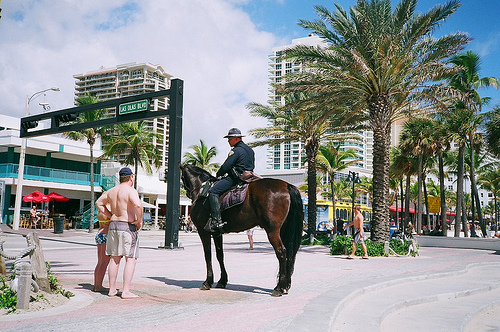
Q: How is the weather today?
A: It is cloudy.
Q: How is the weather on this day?
A: It is cloudy.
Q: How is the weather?
A: It is cloudy.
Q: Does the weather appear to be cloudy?
A: Yes, it is cloudy.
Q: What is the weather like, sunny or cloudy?
A: It is cloudy.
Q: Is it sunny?
A: No, it is cloudy.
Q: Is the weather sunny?
A: No, it is cloudy.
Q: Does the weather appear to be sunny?
A: No, it is cloudy.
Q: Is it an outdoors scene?
A: Yes, it is outdoors.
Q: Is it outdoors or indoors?
A: It is outdoors.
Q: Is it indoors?
A: No, it is outdoors.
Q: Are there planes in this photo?
A: No, there are no planes.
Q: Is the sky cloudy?
A: Yes, the sky is cloudy.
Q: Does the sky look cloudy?
A: Yes, the sky is cloudy.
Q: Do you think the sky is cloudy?
A: Yes, the sky is cloudy.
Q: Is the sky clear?
A: No, the sky is cloudy.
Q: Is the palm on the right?
A: Yes, the palm is on the right of the image.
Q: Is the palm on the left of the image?
A: No, the palm is on the right of the image.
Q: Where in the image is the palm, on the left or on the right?
A: The palm is on the right of the image.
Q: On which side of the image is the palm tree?
A: The palm tree is on the right of the image.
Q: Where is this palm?
A: The palm is on the street.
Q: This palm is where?
A: The palm is on the street.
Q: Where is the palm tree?
A: The palm is on the street.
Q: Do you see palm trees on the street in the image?
A: Yes, there is a palm tree on the street.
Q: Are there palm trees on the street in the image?
A: Yes, there is a palm tree on the street.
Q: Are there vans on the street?
A: No, there is a palm tree on the street.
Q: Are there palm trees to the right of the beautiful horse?
A: Yes, there is a palm tree to the right of the horse.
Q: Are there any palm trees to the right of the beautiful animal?
A: Yes, there is a palm tree to the right of the horse.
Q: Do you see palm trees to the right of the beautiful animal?
A: Yes, there is a palm tree to the right of the horse.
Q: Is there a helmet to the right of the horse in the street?
A: No, there is a palm tree to the right of the horse.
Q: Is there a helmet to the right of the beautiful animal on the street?
A: No, there is a palm tree to the right of the horse.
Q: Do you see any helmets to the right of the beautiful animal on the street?
A: No, there is a palm tree to the right of the horse.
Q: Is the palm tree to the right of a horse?
A: Yes, the palm tree is to the right of a horse.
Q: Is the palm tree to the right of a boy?
A: No, the palm tree is to the right of a horse.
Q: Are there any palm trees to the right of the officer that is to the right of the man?
A: Yes, there is a palm tree to the right of the officer.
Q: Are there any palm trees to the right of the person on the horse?
A: Yes, there is a palm tree to the right of the officer.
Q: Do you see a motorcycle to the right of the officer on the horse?
A: No, there is a palm tree to the right of the officer.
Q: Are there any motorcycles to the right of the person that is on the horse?
A: No, there is a palm tree to the right of the officer.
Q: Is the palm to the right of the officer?
A: Yes, the palm is to the right of the officer.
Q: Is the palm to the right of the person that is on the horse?
A: Yes, the palm is to the right of the officer.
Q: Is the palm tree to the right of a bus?
A: No, the palm tree is to the right of the officer.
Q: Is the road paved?
A: Yes, the road is paved.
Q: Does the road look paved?
A: Yes, the road is paved.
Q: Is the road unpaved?
A: No, the road is paved.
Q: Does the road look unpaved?
A: No, the road is paved.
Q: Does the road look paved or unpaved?
A: The road is paved.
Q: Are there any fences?
A: No, there are no fences.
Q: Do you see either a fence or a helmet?
A: No, there are no fences or helmets.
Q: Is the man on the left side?
A: Yes, the man is on the left of the image.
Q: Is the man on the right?
A: No, the man is on the left of the image.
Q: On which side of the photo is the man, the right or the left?
A: The man is on the left of the image.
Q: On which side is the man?
A: The man is on the left of the image.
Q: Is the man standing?
A: Yes, the man is standing.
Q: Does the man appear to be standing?
A: Yes, the man is standing.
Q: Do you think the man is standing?
A: Yes, the man is standing.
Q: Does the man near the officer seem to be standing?
A: Yes, the man is standing.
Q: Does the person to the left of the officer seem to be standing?
A: Yes, the man is standing.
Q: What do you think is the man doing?
A: The man is standing.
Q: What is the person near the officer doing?
A: The man is standing.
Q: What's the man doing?
A: The man is standing.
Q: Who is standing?
A: The man is standing.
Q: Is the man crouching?
A: No, the man is standing.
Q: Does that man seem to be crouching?
A: No, the man is standing.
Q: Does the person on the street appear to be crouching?
A: No, the man is standing.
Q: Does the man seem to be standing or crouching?
A: The man is standing.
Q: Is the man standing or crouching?
A: The man is standing.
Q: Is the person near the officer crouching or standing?
A: The man is standing.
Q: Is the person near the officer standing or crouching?
A: The man is standing.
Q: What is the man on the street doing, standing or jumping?
A: The man is standing.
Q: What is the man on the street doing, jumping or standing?
A: The man is standing.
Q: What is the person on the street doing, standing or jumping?
A: The man is standing.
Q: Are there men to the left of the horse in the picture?
A: Yes, there is a man to the left of the horse.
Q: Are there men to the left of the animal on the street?
A: Yes, there is a man to the left of the horse.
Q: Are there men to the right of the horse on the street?
A: No, the man is to the left of the horse.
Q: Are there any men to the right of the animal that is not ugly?
A: No, the man is to the left of the horse.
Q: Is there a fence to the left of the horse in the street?
A: No, there is a man to the left of the horse.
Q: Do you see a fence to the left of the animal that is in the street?
A: No, there is a man to the left of the horse.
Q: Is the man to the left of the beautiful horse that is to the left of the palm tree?
A: Yes, the man is to the left of the horse.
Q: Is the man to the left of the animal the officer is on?
A: Yes, the man is to the left of the horse.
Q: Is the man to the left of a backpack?
A: No, the man is to the left of the horse.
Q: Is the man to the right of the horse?
A: No, the man is to the left of the horse.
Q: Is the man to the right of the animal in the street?
A: No, the man is to the left of the horse.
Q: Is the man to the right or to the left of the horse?
A: The man is to the left of the horse.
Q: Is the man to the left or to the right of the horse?
A: The man is to the left of the horse.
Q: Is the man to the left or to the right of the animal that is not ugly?
A: The man is to the left of the horse.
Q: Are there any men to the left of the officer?
A: Yes, there is a man to the left of the officer.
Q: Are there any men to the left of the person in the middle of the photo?
A: Yes, there is a man to the left of the officer.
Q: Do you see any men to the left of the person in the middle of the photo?
A: Yes, there is a man to the left of the officer.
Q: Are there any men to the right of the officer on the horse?
A: No, the man is to the left of the officer.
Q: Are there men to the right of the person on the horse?
A: No, the man is to the left of the officer.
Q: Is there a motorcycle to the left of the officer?
A: No, there is a man to the left of the officer.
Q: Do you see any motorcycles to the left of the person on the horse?
A: No, there is a man to the left of the officer.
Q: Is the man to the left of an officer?
A: Yes, the man is to the left of an officer.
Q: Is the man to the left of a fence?
A: No, the man is to the left of an officer.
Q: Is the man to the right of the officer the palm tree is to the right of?
A: No, the man is to the left of the officer.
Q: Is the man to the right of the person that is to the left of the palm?
A: No, the man is to the left of the officer.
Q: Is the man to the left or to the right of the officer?
A: The man is to the left of the officer.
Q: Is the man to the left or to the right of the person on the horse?
A: The man is to the left of the officer.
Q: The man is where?
A: The man is on the street.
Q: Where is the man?
A: The man is on the street.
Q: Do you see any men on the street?
A: Yes, there is a man on the street.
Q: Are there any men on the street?
A: Yes, there is a man on the street.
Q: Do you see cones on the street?
A: No, there is a man on the street.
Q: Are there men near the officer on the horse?
A: Yes, there is a man near the officer.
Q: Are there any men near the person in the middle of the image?
A: Yes, there is a man near the officer.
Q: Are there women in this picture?
A: No, there are no women.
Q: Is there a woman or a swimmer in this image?
A: No, there are no women or swimmers.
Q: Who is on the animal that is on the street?
A: The officer is on the horse.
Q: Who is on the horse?
A: The officer is on the horse.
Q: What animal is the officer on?
A: The officer is on the horse.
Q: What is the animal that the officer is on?
A: The animal is a horse.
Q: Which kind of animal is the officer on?
A: The officer is on the horse.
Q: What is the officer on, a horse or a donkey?
A: The officer is on a horse.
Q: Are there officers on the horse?
A: Yes, there is an officer on the horse.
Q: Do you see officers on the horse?
A: Yes, there is an officer on the horse.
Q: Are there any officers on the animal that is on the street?
A: Yes, there is an officer on the horse.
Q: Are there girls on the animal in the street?
A: No, there is an officer on the horse.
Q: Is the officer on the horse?
A: Yes, the officer is on the horse.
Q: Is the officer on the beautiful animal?
A: Yes, the officer is on the horse.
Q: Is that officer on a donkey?
A: No, the officer is on the horse.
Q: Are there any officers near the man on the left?
A: Yes, there is an officer near the man.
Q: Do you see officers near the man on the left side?
A: Yes, there is an officer near the man.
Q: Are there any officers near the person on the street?
A: Yes, there is an officer near the man.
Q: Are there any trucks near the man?
A: No, there is an officer near the man.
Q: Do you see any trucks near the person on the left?
A: No, there is an officer near the man.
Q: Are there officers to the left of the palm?
A: Yes, there is an officer to the left of the palm.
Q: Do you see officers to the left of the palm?
A: Yes, there is an officer to the left of the palm.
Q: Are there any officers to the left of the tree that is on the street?
A: Yes, there is an officer to the left of the palm.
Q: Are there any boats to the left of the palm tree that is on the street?
A: No, there is an officer to the left of the palm tree.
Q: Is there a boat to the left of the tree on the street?
A: No, there is an officer to the left of the palm tree.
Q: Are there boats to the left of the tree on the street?
A: No, there is an officer to the left of the palm tree.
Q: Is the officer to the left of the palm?
A: Yes, the officer is to the left of the palm.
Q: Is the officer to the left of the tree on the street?
A: Yes, the officer is to the left of the palm.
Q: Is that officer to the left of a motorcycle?
A: No, the officer is to the left of the palm.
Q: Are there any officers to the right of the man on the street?
A: Yes, there is an officer to the right of the man.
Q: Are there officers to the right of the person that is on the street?
A: Yes, there is an officer to the right of the man.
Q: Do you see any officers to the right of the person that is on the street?
A: Yes, there is an officer to the right of the man.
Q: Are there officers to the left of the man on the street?
A: No, the officer is to the right of the man.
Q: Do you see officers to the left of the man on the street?
A: No, the officer is to the right of the man.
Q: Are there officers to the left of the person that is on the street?
A: No, the officer is to the right of the man.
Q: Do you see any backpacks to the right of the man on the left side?
A: No, there is an officer to the right of the man.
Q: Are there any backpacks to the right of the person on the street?
A: No, there is an officer to the right of the man.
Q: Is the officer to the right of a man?
A: Yes, the officer is to the right of a man.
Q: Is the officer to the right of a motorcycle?
A: No, the officer is to the right of a man.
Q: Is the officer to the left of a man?
A: No, the officer is to the right of a man.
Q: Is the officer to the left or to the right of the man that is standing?
A: The officer is to the right of the man.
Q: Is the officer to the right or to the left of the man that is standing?
A: The officer is to the right of the man.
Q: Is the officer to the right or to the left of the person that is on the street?
A: The officer is to the right of the man.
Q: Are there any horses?
A: Yes, there is a horse.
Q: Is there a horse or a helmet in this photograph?
A: Yes, there is a horse.